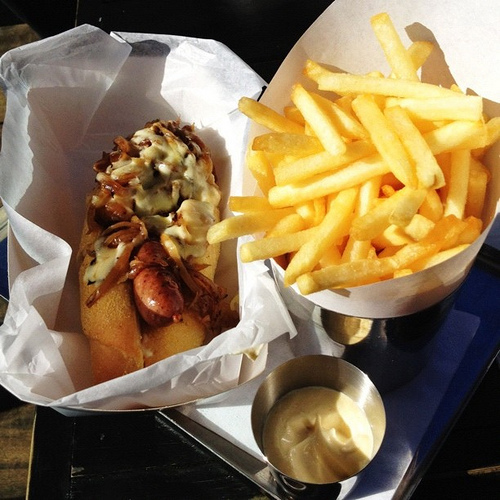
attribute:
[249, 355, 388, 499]
container — metal, round, small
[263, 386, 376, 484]
sauce — dipping, creamy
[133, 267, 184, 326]
hot dog — loaded, meal, cooked, smothered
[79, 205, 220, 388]
bun — bread, white, brown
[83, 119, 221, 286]
cheese — melted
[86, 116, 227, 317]
onion — fried, brown, caramelized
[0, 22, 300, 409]
paper — waxed, small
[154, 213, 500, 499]
tray — metal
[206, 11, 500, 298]
fries — meal, golden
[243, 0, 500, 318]
container — cardboard, white, paper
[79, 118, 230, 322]
toppings — gooey